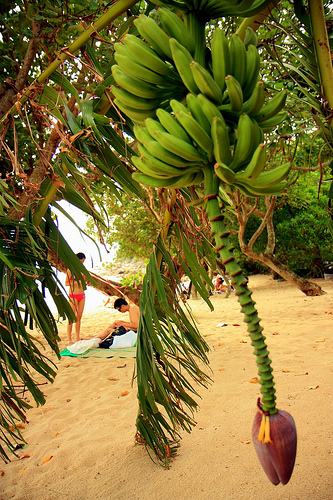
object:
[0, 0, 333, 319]
tree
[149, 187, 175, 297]
palm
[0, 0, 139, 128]
palm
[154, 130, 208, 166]
banana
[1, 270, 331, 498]
beach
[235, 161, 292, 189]
banana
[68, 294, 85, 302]
bikini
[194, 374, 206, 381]
leaves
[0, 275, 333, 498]
groves sand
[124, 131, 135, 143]
sky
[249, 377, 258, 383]
groves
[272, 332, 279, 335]
groves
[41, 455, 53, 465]
groves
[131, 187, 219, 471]
banana leaf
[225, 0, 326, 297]
tree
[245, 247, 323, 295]
trunk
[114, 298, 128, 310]
hair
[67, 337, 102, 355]
towel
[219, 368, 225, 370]
groves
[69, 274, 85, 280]
bikini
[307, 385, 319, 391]
leaves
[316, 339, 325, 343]
leaves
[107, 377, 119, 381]
leaves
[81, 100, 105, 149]
leaves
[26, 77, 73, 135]
leaves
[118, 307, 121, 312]
sunglasses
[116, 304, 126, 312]
man's face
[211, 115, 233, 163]
bananas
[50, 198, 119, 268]
light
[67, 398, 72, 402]
grove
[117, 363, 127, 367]
grove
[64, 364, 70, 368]
grove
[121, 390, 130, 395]
grove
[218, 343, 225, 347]
grove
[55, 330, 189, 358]
blanket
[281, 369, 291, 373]
groves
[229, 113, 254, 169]
bananas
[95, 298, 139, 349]
guy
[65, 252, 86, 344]
girl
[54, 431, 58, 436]
groves